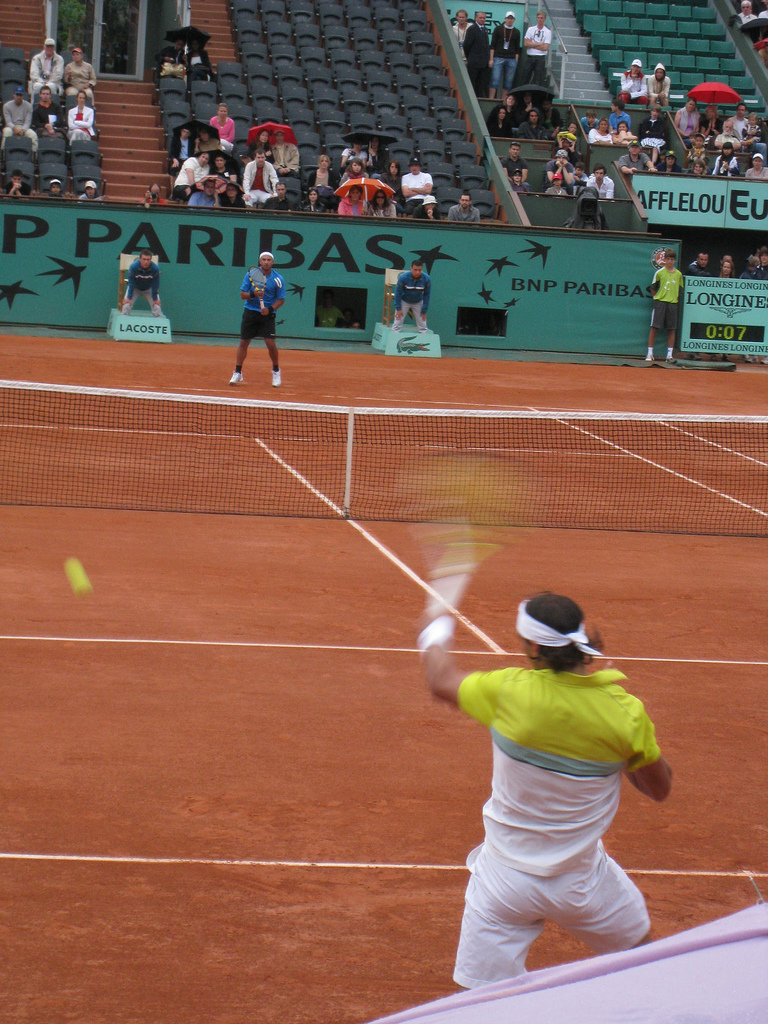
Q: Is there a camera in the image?
A: Yes, there is a camera.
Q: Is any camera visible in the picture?
A: Yes, there is a camera.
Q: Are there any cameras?
A: Yes, there is a camera.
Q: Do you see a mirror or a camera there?
A: Yes, there is a camera.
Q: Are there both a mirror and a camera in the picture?
A: No, there is a camera but no mirrors.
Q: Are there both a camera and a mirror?
A: No, there is a camera but no mirrors.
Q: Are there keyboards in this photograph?
A: No, there are no keyboards.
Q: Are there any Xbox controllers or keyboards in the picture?
A: No, there are no keyboards or Xbox controllers.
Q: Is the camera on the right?
A: Yes, the camera is on the right of the image.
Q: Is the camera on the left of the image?
A: No, the camera is on the right of the image.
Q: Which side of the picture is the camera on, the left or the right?
A: The camera is on the right of the image.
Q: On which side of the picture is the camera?
A: The camera is on the right of the image.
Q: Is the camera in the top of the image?
A: Yes, the camera is in the top of the image.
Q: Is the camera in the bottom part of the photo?
A: No, the camera is in the top of the image.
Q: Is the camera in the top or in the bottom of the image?
A: The camera is in the top of the image.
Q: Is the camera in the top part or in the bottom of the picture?
A: The camera is in the top of the image.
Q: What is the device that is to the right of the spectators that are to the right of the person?
A: The device is a camera.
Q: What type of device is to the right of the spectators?
A: The device is a camera.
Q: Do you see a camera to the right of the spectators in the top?
A: Yes, there is a camera to the right of the spectators.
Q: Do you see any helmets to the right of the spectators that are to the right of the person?
A: No, there is a camera to the right of the spectators.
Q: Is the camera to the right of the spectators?
A: Yes, the camera is to the right of the spectators.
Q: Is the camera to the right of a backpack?
A: No, the camera is to the right of the umbrella.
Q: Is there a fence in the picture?
A: No, there are no fences.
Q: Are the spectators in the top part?
A: Yes, the spectators are in the top of the image.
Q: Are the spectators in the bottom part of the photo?
A: No, the spectators are in the top of the image.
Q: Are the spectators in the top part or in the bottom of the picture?
A: The spectators are in the top of the image.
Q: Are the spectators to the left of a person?
A: Yes, the spectators are to the left of a person.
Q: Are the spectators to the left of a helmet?
A: No, the spectators are to the left of a person.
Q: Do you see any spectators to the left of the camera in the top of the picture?
A: Yes, there are spectators to the left of the camera.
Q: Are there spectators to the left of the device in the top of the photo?
A: Yes, there are spectators to the left of the camera.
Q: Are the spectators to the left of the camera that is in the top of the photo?
A: Yes, the spectators are to the left of the camera.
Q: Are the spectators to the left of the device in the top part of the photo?
A: Yes, the spectators are to the left of the camera.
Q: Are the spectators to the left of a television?
A: No, the spectators are to the left of the camera.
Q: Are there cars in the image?
A: No, there are no cars.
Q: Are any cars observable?
A: No, there are no cars.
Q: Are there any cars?
A: No, there are no cars.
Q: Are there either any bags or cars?
A: No, there are no cars or bags.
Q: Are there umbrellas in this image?
A: Yes, there is an umbrella.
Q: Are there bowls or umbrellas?
A: Yes, there is an umbrella.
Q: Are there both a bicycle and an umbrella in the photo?
A: No, there is an umbrella but no bicycles.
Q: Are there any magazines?
A: No, there are no magazines.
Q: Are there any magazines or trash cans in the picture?
A: No, there are no magazines or trash cans.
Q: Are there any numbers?
A: Yes, there are numbers.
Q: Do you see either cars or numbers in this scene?
A: Yes, there are numbers.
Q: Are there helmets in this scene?
A: No, there are no helmets.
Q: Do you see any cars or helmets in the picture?
A: No, there are no helmets or cars.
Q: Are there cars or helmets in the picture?
A: No, there are no helmets or cars.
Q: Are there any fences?
A: No, there are no fences.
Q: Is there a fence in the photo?
A: No, there are no fences.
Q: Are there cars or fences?
A: No, there are no fences or cars.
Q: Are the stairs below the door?
A: Yes, the stairs are below the door.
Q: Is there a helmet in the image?
A: No, there are no helmets.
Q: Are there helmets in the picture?
A: No, there are no helmets.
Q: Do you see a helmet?
A: No, there are no helmets.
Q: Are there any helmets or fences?
A: No, there are no helmets or fences.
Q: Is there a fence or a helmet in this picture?
A: No, there are no helmets or fences.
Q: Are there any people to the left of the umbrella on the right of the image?
A: Yes, there is a person to the left of the umbrella.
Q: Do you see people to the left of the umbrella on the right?
A: Yes, there is a person to the left of the umbrella.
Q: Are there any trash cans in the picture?
A: No, there are no trash cans.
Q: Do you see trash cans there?
A: No, there are no trash cans.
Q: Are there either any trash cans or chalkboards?
A: No, there are no trash cans or chalkboards.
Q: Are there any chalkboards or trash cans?
A: No, there are no trash cans or chalkboards.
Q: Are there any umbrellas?
A: Yes, there is an umbrella.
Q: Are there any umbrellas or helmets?
A: Yes, there is an umbrella.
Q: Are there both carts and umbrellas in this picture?
A: No, there is an umbrella but no carts.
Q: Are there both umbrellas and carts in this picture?
A: No, there is an umbrella but no carts.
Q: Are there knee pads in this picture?
A: No, there are no knee pads.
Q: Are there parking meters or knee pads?
A: No, there are no knee pads or parking meters.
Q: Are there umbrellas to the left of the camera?
A: Yes, there is an umbrella to the left of the camera.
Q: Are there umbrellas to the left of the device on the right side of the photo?
A: Yes, there is an umbrella to the left of the camera.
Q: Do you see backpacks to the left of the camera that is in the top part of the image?
A: No, there is an umbrella to the left of the camera.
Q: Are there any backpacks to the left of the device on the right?
A: No, there is an umbrella to the left of the camera.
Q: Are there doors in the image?
A: Yes, there is a door.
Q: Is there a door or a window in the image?
A: Yes, there is a door.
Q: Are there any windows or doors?
A: Yes, there is a door.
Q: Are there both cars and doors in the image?
A: No, there is a door but no cars.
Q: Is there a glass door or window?
A: Yes, there is a glass door.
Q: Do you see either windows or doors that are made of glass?
A: Yes, the door is made of glass.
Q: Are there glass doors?
A: Yes, there is a door that is made of glass.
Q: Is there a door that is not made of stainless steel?
A: Yes, there is a door that is made of glass.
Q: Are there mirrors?
A: No, there are no mirrors.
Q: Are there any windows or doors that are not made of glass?
A: No, there is a door but it is made of glass.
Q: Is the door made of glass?
A: Yes, the door is made of glass.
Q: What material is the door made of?
A: The door is made of glass.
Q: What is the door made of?
A: The door is made of glass.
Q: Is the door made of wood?
A: No, the door is made of glass.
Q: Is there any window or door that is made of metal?
A: No, there is a door but it is made of glass.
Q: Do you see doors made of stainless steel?
A: No, there is a door but it is made of glass.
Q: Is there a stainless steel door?
A: No, there is a door but it is made of glass.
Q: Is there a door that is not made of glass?
A: No, there is a door but it is made of glass.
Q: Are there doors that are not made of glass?
A: No, there is a door but it is made of glass.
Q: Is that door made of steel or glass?
A: The door is made of glass.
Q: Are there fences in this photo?
A: No, there are no fences.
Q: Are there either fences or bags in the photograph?
A: No, there are no fences or bags.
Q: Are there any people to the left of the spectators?
A: Yes, there is a person to the left of the spectators.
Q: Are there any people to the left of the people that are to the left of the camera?
A: Yes, there is a person to the left of the spectators.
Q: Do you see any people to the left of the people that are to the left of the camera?
A: Yes, there is a person to the left of the spectators.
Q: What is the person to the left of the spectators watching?
A: The person is watching the match.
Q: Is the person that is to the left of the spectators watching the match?
A: Yes, the person is watching the match.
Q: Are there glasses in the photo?
A: No, there are no glasses.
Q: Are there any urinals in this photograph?
A: No, there are no urinals.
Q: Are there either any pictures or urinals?
A: No, there are no urinals or pictures.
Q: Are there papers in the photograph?
A: No, there are no papers.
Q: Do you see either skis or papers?
A: No, there are no papers or skis.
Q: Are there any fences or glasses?
A: No, there are no fences or glasses.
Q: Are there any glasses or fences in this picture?
A: No, there are no fences or glasses.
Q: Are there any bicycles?
A: No, there are no bicycles.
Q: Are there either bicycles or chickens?
A: No, there are no bicycles or chickens.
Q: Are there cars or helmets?
A: No, there are no helmets or cars.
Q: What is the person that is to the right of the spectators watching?
A: The person is watching the match.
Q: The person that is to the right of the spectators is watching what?
A: The person is watching the match.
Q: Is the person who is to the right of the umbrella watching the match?
A: Yes, the person is watching the match.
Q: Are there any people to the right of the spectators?
A: Yes, there is a person to the right of the spectators.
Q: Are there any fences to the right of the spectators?
A: No, there is a person to the right of the spectators.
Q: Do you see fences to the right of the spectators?
A: No, there is a person to the right of the spectators.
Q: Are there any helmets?
A: No, there are no helmets.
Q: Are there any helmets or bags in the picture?
A: No, there are no helmets or bags.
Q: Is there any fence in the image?
A: No, there are no fences.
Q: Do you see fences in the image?
A: No, there are no fences.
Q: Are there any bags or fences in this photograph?
A: No, there are no fences or bags.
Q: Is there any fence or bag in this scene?
A: No, there are no fences or bags.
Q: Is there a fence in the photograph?
A: No, there are no fences.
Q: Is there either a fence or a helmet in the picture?
A: No, there are no fences or helmets.